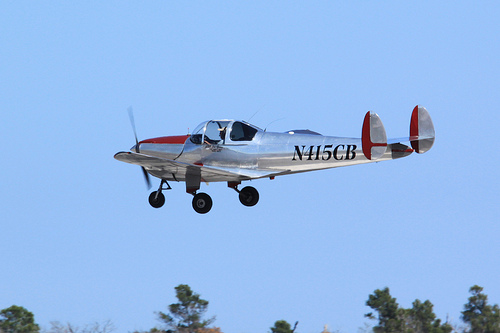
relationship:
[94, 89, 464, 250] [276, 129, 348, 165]
plane has number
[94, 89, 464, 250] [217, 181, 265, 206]
plane has tire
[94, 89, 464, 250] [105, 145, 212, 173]
plane has wing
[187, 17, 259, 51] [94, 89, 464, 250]
sky has plane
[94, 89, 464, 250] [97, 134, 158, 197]
aircraft has propeller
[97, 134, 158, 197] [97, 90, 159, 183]
propeller has blades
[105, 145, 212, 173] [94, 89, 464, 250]
wing of aircraft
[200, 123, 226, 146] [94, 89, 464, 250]
man of aircraft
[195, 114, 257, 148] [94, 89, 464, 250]
window of aircraft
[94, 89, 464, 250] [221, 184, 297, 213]
plane has wheel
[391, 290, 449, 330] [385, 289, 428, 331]
tree with leaves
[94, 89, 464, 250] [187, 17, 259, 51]
plane in sky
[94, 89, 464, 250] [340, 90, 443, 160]
plane has tail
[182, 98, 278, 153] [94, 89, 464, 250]
cockpit of plane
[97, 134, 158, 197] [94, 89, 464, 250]
propeller of aircraft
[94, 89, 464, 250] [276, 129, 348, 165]
aircraft has number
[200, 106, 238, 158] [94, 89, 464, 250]
man in plane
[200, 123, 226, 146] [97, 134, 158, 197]
man and propeller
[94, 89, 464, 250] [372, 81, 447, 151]
plane has fin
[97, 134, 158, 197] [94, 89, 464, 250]
propeller on plane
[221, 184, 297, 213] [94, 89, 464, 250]
wheel on plane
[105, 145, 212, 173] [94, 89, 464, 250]
wing on plane